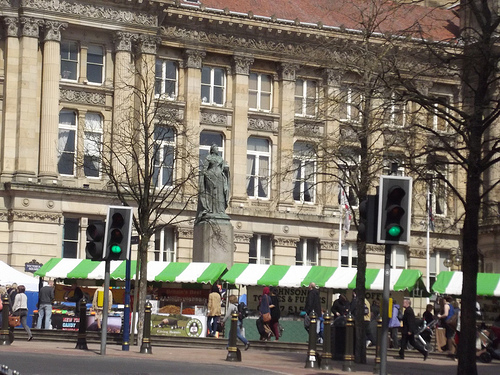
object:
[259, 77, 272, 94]
windows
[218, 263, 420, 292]
roof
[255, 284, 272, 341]
people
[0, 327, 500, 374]
sidewalk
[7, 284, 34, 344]
woman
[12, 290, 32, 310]
shirt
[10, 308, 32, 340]
pants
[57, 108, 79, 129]
window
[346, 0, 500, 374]
tree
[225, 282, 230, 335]
pole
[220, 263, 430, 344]
business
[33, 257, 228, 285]
awning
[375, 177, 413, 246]
traffic lights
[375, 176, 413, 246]
frame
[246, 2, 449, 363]
tree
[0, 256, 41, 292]
awning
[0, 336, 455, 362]
steps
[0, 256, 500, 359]
flea market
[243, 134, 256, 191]
curtains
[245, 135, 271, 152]
windows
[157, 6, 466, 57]
roof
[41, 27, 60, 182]
columns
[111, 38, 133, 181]
columns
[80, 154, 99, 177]
window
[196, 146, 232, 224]
statue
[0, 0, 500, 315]
building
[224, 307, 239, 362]
pole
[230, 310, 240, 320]
trim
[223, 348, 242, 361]
trim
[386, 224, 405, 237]
light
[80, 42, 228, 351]
tree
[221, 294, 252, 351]
woman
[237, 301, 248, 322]
backpack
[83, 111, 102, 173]
curtain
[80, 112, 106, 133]
window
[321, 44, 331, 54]
leaves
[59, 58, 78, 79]
window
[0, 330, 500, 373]
road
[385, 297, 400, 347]
woman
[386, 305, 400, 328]
coat